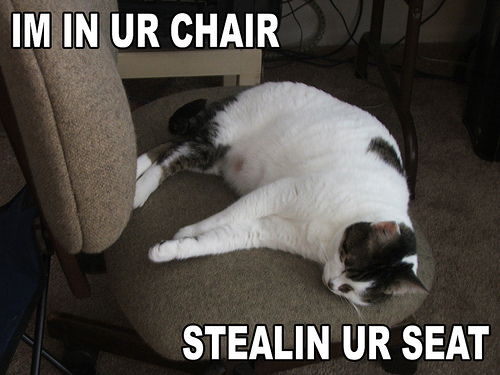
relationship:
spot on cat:
[351, 110, 423, 192] [116, 51, 463, 321]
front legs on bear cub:
[143, 195, 303, 266] [132, 81, 431, 324]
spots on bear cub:
[164, 93, 235, 171] [132, 81, 431, 324]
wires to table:
[292, 9, 456, 81] [141, 16, 466, 116]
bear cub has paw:
[132, 81, 431, 324] [146, 233, 179, 265]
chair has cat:
[8, 32, 478, 328] [153, 62, 452, 309]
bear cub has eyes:
[132, 81, 431, 324] [341, 254, 359, 276]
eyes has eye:
[341, 254, 359, 276] [335, 254, 355, 274]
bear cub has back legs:
[132, 81, 431, 324] [131, 136, 206, 210]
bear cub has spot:
[132, 81, 431, 324] [358, 128, 404, 178]